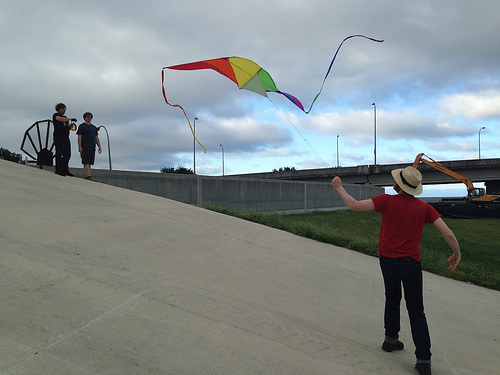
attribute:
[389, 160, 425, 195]
hat — white 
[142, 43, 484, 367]
kite — rainbow 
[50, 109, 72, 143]
shirt — black 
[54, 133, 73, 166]
pants — black 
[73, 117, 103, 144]
shirt — black 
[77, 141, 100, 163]
shorts — black 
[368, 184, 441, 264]
shirt — red 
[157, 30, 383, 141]
kite — red 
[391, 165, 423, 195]
hat — beige, straw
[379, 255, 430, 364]
pants — black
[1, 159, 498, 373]
slope — paved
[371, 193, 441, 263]
shirt — red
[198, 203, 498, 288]
yard — grassy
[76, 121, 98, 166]
clothing — black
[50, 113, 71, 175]
clothing — black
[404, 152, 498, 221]
crane — Orange construction , yellow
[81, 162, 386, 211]
fence — Long wooden 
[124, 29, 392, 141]
kite — Flying rainbow , Rainbow  ,  triangular yellow part , flying, airborne, colorful, red, yellow, green, multi-colored, flowing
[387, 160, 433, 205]
hat — white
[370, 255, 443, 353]
pants — dark , black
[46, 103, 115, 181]
people — standing , background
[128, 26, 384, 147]
object — air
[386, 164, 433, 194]
cap — white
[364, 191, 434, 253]
shirt — red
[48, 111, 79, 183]
clothes — black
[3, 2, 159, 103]
sky — cloudy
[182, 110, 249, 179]
posts — tall